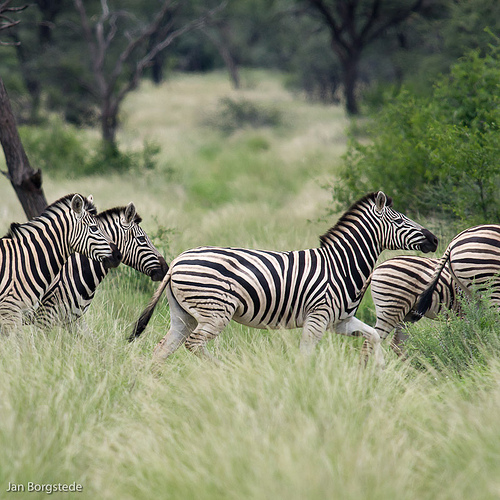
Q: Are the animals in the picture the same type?
A: Yes, all the animals are zebras.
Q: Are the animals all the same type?
A: Yes, all the animals are zebras.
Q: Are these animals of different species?
A: No, all the animals are zebras.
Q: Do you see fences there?
A: No, there are no fences.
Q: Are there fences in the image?
A: No, there are no fences.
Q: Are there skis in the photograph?
A: No, there are no skis.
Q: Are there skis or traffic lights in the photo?
A: No, there are no skis or traffic lights.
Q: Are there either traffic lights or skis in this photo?
A: No, there are no skis or traffic lights.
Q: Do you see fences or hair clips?
A: No, there are no fences or hair clips.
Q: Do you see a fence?
A: No, there are no fences.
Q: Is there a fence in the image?
A: No, there are no fences.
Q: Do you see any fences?
A: No, there are no fences.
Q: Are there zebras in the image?
A: Yes, there are zebras.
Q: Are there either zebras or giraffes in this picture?
A: Yes, there are zebras.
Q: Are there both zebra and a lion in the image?
A: No, there are zebras but no lions.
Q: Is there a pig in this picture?
A: No, there are no pigs.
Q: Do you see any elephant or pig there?
A: No, there are no pigs or elephants.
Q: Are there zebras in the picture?
A: Yes, there are zebras.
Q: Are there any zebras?
A: Yes, there are zebras.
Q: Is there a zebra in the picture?
A: Yes, there are zebras.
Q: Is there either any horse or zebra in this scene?
A: Yes, there are zebras.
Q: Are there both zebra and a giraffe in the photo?
A: No, there are zebras but no giraffes.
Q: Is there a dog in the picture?
A: No, there are no dogs.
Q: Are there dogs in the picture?
A: No, there are no dogs.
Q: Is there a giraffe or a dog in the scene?
A: No, there are no dogs or giraffes.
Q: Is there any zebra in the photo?
A: Yes, there are zebras.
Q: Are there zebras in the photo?
A: Yes, there are zebras.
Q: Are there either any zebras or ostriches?
A: Yes, there are zebras.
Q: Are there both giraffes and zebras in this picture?
A: No, there are zebras but no giraffes.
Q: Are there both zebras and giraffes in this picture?
A: No, there are zebras but no giraffes.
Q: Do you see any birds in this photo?
A: No, there are no birds.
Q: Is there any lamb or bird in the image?
A: No, there are no birds or lambs.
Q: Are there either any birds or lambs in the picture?
A: No, there are no birds or lambs.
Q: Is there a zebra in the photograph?
A: Yes, there are zebras.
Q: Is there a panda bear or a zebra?
A: Yes, there are zebras.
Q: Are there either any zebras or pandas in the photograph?
A: Yes, there are zebras.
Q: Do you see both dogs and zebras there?
A: No, there are zebras but no dogs.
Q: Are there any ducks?
A: No, there are no ducks.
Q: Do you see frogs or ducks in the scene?
A: No, there are no ducks or frogs.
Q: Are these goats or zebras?
A: These are zebras.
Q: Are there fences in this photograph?
A: No, there are no fences.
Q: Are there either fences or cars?
A: No, there are no fences or cars.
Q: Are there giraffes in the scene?
A: No, there are no giraffes.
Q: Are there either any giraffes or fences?
A: No, there are no giraffes or fences.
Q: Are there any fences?
A: No, there are no fences.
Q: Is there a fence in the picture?
A: No, there are no fences.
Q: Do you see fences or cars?
A: No, there are no fences or cars.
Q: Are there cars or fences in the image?
A: No, there are no fences or cars.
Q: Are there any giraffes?
A: No, there are no giraffes.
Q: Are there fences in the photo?
A: No, there are no fences.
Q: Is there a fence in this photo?
A: No, there are no fences.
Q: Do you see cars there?
A: No, there are no cars.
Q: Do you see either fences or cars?
A: No, there are no cars or fences.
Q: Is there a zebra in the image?
A: Yes, there are zebras.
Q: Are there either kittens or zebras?
A: Yes, there are zebras.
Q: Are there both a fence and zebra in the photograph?
A: No, there are zebras but no fences.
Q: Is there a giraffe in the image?
A: No, there are no giraffes.